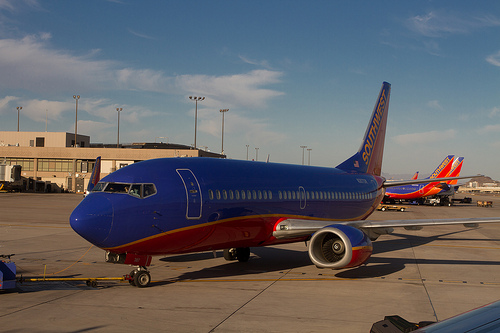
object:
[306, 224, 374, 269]
engine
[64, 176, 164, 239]
cockpit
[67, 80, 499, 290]
plane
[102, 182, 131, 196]
windows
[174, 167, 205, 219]
door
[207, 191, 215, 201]
window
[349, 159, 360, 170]
company logo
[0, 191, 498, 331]
runway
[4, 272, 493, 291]
stripes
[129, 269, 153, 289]
wheel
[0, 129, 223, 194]
building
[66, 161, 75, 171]
window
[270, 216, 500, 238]
wing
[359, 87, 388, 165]
writing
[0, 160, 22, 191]
truck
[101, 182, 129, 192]
windshield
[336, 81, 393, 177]
tail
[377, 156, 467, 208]
planes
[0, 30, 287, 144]
clouds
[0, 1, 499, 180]
sky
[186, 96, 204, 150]
lightpost